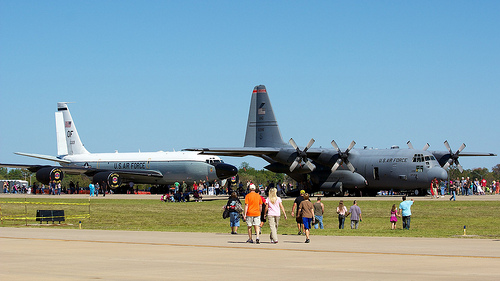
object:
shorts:
[303, 217, 312, 229]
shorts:
[230, 212, 240, 227]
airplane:
[14, 102, 238, 195]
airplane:
[197, 85, 497, 197]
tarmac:
[1, 226, 500, 281]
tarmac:
[2, 192, 500, 202]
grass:
[1, 196, 499, 239]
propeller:
[289, 138, 317, 172]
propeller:
[331, 140, 356, 174]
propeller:
[441, 140, 467, 174]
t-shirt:
[399, 200, 413, 216]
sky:
[2, 0, 500, 172]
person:
[222, 192, 246, 234]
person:
[244, 184, 263, 244]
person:
[264, 188, 287, 243]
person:
[297, 193, 316, 243]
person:
[336, 200, 348, 230]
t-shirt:
[244, 192, 263, 217]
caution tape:
[0, 202, 90, 221]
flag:
[65, 121, 71, 128]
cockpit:
[206, 157, 224, 164]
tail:
[183, 85, 284, 160]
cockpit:
[412, 153, 436, 163]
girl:
[390, 204, 401, 230]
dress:
[390, 210, 398, 222]